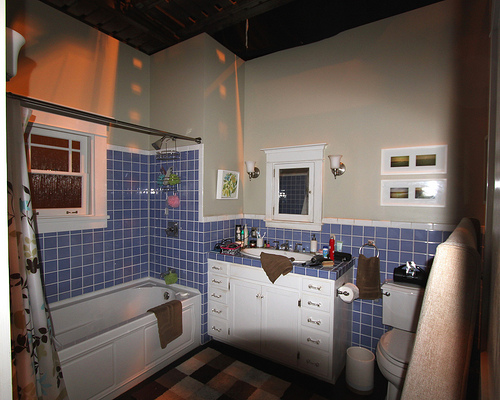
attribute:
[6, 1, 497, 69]
ceiling — slatted